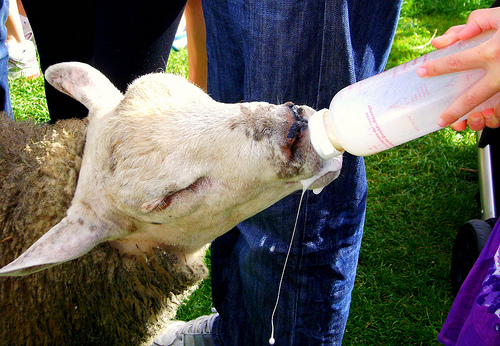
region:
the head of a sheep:
[0, 53, 362, 288]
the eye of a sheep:
[139, 170, 211, 221]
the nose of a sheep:
[276, 93, 313, 165]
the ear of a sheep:
[36, 59, 126, 114]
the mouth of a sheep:
[293, 100, 351, 192]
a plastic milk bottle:
[299, 26, 498, 166]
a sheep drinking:
[0, 50, 362, 345]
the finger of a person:
[415, 45, 482, 82]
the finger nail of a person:
[413, 63, 430, 80]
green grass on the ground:
[328, 0, 498, 344]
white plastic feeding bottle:
[304, 22, 499, 187]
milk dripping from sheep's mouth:
[247, 153, 359, 344]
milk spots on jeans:
[255, 228, 280, 253]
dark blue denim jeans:
[185, 3, 420, 333]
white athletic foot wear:
[141, 306, 243, 344]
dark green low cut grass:
[4, 3, 494, 340]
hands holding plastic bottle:
[408, 5, 498, 137]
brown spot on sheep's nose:
[220, 90, 295, 150]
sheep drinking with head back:
[2, 57, 349, 342]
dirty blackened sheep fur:
[5, 236, 216, 344]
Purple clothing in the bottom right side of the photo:
[438, 202, 497, 342]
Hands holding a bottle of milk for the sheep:
[420, 6, 499, 133]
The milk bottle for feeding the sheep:
[306, 33, 496, 159]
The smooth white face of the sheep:
[2, 60, 345, 276]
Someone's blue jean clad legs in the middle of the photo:
[198, 9, 403, 343]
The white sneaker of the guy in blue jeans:
[152, 310, 217, 342]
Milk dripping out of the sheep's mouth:
[266, 178, 336, 342]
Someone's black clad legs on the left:
[21, 5, 188, 120]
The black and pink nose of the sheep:
[285, 99, 308, 156]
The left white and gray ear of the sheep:
[38, 57, 119, 124]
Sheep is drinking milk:
[8, 48, 498, 325]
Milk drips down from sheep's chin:
[256, 106, 337, 344]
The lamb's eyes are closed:
[141, 178, 226, 219]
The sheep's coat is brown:
[1, 123, 57, 222]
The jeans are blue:
[216, 2, 328, 92]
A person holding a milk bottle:
[308, 3, 497, 160]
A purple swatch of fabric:
[438, 204, 495, 343]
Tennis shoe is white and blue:
[151, 310, 233, 343]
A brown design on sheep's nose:
[221, 100, 277, 141]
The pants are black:
[33, 1, 165, 60]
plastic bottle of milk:
[301, 29, 494, 181]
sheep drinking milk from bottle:
[5, 50, 340, 345]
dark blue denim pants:
[187, 2, 419, 344]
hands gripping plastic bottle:
[413, 1, 498, 149]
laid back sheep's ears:
[0, 54, 127, 319]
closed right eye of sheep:
[135, 173, 210, 228]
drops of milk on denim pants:
[255, 227, 280, 257]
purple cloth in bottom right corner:
[432, 208, 498, 341]